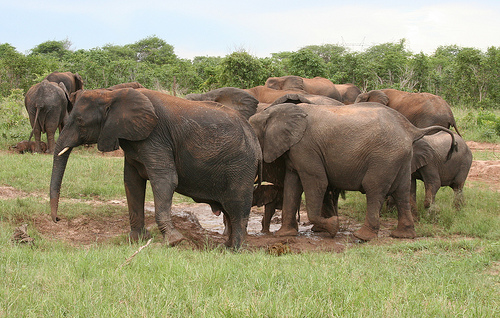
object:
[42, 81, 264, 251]
elephant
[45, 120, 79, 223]
trunk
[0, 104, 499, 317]
grass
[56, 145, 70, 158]
tusk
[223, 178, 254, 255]
back legs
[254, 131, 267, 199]
tail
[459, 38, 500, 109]
trees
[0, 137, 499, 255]
dirt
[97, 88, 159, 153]
ear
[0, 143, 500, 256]
mud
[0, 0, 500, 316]
field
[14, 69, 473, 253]
herd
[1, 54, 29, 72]
leaves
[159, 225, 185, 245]
foot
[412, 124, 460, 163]
tail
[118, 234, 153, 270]
stick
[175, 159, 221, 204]
stomach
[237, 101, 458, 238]
elephants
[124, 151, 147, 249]
front legs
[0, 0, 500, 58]
sky